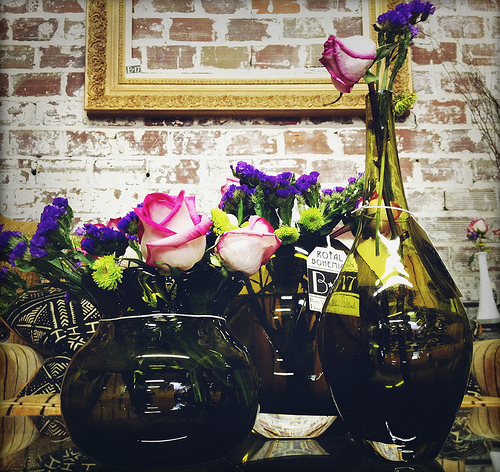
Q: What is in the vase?
A: Flowers.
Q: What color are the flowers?
A: Purple and pink.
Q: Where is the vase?
A: On a table.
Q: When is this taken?
A: During the daytime.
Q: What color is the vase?
A: Brown.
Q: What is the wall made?
A: Brick.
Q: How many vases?
A: Three.